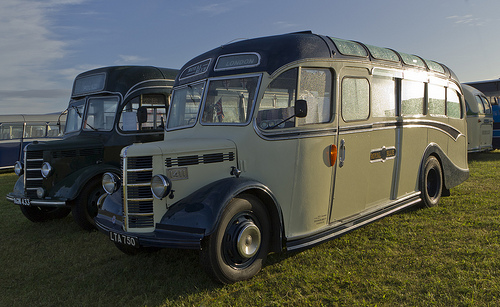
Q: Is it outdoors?
A: Yes, it is outdoors.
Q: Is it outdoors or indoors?
A: It is outdoors.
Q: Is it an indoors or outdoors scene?
A: It is outdoors.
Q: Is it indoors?
A: No, it is outdoors.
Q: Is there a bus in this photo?
A: Yes, there is a bus.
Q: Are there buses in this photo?
A: Yes, there is a bus.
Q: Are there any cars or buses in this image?
A: Yes, there is a bus.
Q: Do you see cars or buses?
A: Yes, there is a bus.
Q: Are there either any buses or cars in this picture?
A: Yes, there is a bus.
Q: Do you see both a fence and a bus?
A: No, there is a bus but no fences.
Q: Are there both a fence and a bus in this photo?
A: No, there is a bus but no fences.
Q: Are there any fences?
A: No, there are no fences.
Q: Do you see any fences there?
A: No, there are no fences.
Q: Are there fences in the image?
A: No, there are no fences.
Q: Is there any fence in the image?
A: No, there are no fences.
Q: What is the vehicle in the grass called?
A: The vehicle is a bus.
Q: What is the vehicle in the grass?
A: The vehicle is a bus.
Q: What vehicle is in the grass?
A: The vehicle is a bus.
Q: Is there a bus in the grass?
A: Yes, there is a bus in the grass.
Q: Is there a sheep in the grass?
A: No, there is a bus in the grass.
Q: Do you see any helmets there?
A: No, there are no helmets.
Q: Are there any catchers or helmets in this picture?
A: No, there are no helmets or catchers.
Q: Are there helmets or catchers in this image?
A: No, there are no helmets or catchers.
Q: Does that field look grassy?
A: Yes, the field is grassy.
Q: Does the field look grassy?
A: Yes, the field is grassy.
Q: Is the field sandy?
A: No, the field is grassy.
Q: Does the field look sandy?
A: No, the field is grassy.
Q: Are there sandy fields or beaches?
A: No, there is a field but it is grassy.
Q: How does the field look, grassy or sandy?
A: The field is grassy.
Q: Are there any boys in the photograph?
A: No, there are no boys.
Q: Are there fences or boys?
A: No, there are no boys or fences.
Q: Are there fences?
A: No, there are no fences.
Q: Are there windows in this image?
A: Yes, there is a window.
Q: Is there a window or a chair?
A: Yes, there is a window.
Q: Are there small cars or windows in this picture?
A: Yes, there is a small window.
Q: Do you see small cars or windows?
A: Yes, there is a small window.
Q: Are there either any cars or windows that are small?
A: Yes, the window is small.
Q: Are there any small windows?
A: Yes, there is a small window.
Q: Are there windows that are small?
A: Yes, there is a window that is small.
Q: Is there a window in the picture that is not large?
A: Yes, there is a small window.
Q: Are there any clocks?
A: No, there are no clocks.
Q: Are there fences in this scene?
A: No, there are no fences.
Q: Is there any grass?
A: Yes, there is grass.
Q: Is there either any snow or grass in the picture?
A: Yes, there is grass.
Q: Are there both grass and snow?
A: No, there is grass but no snow.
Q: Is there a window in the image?
A: Yes, there is a window.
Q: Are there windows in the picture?
A: Yes, there is a window.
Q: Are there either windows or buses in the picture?
A: Yes, there is a window.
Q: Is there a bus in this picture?
A: Yes, there is a bus.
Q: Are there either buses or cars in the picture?
A: Yes, there is a bus.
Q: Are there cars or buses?
A: Yes, there is a bus.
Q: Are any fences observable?
A: No, there are no fences.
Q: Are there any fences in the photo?
A: No, there are no fences.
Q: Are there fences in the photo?
A: No, there are no fences.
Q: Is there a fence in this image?
A: No, there are no fences.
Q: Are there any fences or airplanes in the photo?
A: No, there are no fences or airplanes.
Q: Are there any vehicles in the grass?
A: Yes, there is a vehicle in the grass.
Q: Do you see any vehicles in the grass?
A: Yes, there is a vehicle in the grass.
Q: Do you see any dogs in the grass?
A: No, there is a vehicle in the grass.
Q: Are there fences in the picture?
A: No, there are no fences.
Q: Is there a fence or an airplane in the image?
A: No, there are no fences or airplanes.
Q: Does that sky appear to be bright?
A: Yes, the sky is bright.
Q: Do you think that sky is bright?
A: Yes, the sky is bright.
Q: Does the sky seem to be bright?
A: Yes, the sky is bright.